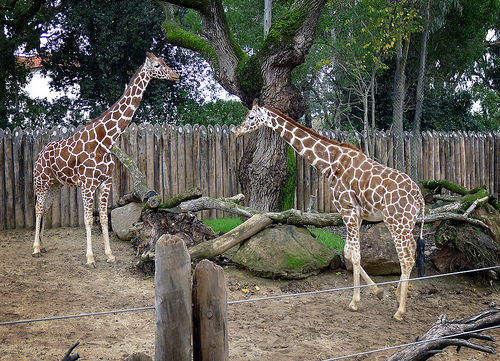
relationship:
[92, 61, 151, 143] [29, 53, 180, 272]
neck on giraffe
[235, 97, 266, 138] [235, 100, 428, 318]
head belonging to giraffe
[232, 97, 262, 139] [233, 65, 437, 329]
head belonging to giraffe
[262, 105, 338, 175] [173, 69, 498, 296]
neck belonging to giraffe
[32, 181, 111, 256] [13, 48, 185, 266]
leg belonging to giraffe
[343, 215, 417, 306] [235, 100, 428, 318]
leg belonging to giraffe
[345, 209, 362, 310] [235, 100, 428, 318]
leg belonging to giraffe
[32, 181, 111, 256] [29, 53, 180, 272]
leg belonging to giraffe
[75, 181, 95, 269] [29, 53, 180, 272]
leg belonging to giraffe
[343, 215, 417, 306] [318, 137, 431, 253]
leg belonging to giraffe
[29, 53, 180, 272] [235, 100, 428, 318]
giraffe standing next to giraffe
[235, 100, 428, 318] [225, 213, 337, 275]
giraffe standing next to rock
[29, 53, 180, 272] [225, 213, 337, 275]
giraffe standing next to rock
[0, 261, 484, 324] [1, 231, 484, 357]
wire spanning fence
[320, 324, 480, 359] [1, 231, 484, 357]
wire spanning fence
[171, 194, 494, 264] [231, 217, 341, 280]
log lying on top of rock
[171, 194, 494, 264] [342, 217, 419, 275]
log lying on top of rock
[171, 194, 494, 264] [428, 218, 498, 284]
log lying on top of rock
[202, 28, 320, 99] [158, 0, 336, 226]
moss covered tree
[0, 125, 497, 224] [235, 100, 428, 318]
fence behind giraffe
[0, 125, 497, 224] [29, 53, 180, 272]
fence behind giraffe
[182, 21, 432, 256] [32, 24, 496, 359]
tree inside giraffe enclosure